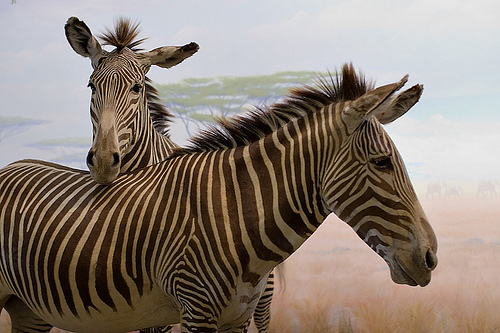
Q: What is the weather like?
A: It is clear.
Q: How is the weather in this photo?
A: It is clear.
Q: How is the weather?
A: It is clear.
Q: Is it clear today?
A: Yes, it is clear.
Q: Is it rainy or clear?
A: It is clear.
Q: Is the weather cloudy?
A: No, it is clear.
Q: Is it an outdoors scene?
A: Yes, it is outdoors.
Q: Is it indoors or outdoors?
A: It is outdoors.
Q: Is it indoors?
A: No, it is outdoors.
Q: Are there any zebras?
A: Yes, there are zebras.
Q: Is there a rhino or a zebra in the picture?
A: Yes, there are zebras.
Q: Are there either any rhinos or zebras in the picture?
A: Yes, there are zebras.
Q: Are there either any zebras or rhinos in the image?
A: Yes, there are zebras.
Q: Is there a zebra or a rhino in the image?
A: Yes, there are zebras.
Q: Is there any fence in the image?
A: No, there are no fences.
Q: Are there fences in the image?
A: No, there are no fences.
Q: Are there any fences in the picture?
A: No, there are no fences.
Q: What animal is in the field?
A: The zebras are in the field.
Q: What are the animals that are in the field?
A: The animals are zebras.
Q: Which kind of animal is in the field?
A: The animals are zebras.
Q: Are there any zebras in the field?
A: Yes, there are zebras in the field.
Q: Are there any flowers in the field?
A: No, there are zebras in the field.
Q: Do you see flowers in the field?
A: No, there are zebras in the field.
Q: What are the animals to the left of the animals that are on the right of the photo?
A: The animals are zebras.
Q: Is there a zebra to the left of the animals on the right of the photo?
A: Yes, there are zebras to the left of the animals.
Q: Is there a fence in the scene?
A: No, there are no fences.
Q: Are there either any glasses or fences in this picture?
A: No, there are no fences or glasses.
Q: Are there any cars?
A: No, there are no cars.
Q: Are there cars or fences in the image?
A: No, there are no cars or fences.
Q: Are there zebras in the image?
A: Yes, there is a zebra.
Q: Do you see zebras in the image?
A: Yes, there is a zebra.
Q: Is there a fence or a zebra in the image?
A: Yes, there is a zebra.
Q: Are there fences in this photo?
A: No, there are no fences.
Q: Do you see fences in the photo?
A: No, there are no fences.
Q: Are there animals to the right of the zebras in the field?
A: Yes, there are animals to the right of the zebras.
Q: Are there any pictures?
A: No, there are no pictures.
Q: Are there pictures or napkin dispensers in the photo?
A: No, there are no pictures or napkin dispensers.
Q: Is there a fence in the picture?
A: No, there are no fences.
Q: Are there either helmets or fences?
A: No, there are no fences or helmets.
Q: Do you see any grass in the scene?
A: Yes, there is grass.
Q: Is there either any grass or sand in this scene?
A: Yes, there is grass.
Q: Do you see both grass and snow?
A: No, there is grass but no snow.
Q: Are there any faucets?
A: No, there are no faucets.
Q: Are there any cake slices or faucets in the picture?
A: No, there are no faucets or cake slices.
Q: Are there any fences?
A: No, there are no fences.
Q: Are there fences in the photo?
A: No, there are no fences.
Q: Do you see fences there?
A: No, there are no fences.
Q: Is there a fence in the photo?
A: No, there are no fences.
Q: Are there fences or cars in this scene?
A: No, there are no fences or cars.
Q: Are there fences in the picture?
A: No, there are no fences.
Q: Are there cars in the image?
A: No, there are no cars.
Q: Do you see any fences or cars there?
A: No, there are no cars or fences.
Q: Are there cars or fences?
A: No, there are no cars or fences.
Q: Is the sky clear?
A: Yes, the sky is clear.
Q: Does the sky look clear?
A: Yes, the sky is clear.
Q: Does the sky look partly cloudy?
A: No, the sky is clear.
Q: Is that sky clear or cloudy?
A: The sky is clear.